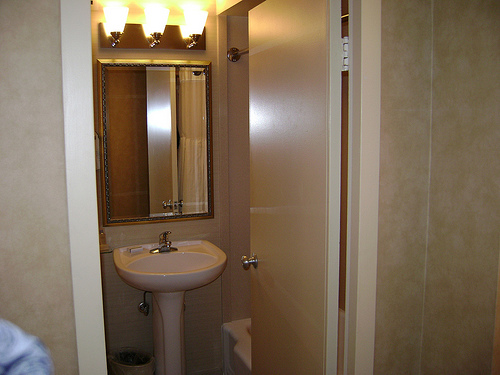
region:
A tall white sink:
[121, 231, 223, 373]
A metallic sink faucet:
[152, 227, 183, 254]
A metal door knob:
[236, 251, 264, 271]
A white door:
[235, 14, 350, 373]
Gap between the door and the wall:
[324, 3, 365, 371]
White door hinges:
[338, 37, 363, 73]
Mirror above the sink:
[85, 62, 226, 225]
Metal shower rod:
[230, 39, 340, 65]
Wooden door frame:
[58, 6, 113, 368]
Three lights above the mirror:
[102, 4, 211, 56]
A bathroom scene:
[14, 13, 486, 370]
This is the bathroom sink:
[114, 223, 231, 366]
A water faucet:
[150, 227, 180, 259]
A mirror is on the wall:
[97, 54, 217, 226]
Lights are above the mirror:
[93, 2, 219, 83]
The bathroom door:
[239, 1, 357, 373]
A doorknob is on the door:
[237, 244, 266, 281]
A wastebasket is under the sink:
[104, 341, 158, 373]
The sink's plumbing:
[129, 285, 185, 318]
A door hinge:
[333, 25, 362, 80]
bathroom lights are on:
[103, 2, 213, 53]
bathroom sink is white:
[108, 235, 258, 372]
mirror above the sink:
[95, 60, 236, 224]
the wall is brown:
[379, 6, 496, 372]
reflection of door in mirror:
[153, 69, 239, 209]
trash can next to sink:
[103, 338, 145, 373]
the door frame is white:
[61, 4, 391, 372]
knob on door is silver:
[230, 247, 266, 277]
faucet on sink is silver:
[145, 227, 181, 261]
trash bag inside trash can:
[108, 338, 152, 373]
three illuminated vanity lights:
[93, 2, 214, 57]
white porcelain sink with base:
[111, 225, 231, 373]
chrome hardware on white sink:
[147, 227, 181, 258]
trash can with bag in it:
[108, 332, 153, 374]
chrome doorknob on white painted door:
[237, 247, 262, 275]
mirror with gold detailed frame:
[95, 51, 221, 229]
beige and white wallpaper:
[394, 95, 485, 335]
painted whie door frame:
[31, 147, 103, 263]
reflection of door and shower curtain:
[163, 72, 201, 187]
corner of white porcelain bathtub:
[212, 307, 251, 373]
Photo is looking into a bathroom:
[11, 1, 489, 365]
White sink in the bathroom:
[109, 225, 241, 372]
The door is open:
[213, 2, 382, 369]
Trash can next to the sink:
[101, 349, 165, 372]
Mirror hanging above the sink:
[97, 42, 218, 232]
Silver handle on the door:
[233, 250, 272, 275]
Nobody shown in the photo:
[24, 0, 492, 367]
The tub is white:
[210, 304, 260, 373]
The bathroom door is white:
[230, 0, 341, 367]